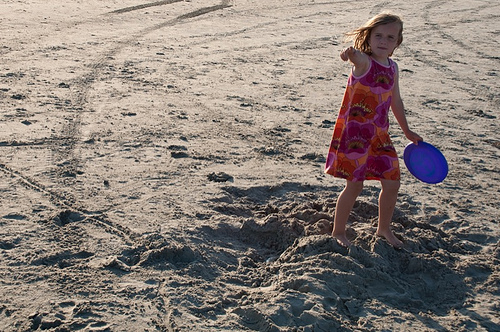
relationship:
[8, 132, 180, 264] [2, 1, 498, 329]
track in sand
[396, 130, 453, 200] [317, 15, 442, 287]
disk held by girl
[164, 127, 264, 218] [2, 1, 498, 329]
shoe prints in sand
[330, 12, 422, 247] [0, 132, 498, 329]
girl and standing in sand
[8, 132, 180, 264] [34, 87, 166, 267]
track in sand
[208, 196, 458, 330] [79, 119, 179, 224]
mounded and sand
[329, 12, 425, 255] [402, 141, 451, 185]
girl holding disk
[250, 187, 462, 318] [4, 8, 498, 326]
sand on ground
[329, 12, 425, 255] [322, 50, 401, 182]
girl wearing dress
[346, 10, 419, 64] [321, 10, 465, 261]
head on girl